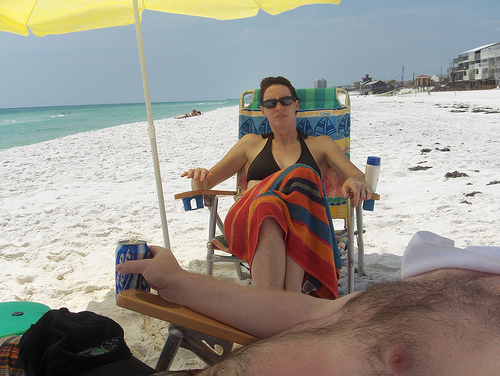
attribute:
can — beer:
[89, 201, 166, 306]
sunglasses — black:
[258, 92, 297, 107]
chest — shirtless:
[186, 258, 495, 374]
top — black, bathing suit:
[243, 126, 323, 182]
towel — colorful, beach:
[224, 163, 338, 296]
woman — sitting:
[193, 69, 380, 270]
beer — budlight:
[117, 239, 164, 304]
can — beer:
[61, 188, 181, 342]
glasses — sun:
[251, 83, 306, 131]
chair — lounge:
[173, 75, 385, 294]